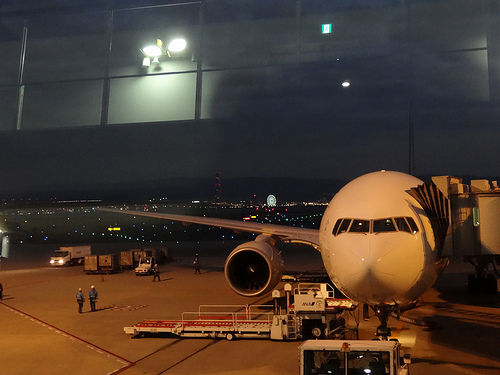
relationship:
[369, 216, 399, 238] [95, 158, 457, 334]
window on plane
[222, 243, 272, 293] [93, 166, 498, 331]
turbine of plane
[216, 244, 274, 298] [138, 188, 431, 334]
engine of plane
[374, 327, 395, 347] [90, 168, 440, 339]
wheel of plane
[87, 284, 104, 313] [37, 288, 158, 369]
person on ground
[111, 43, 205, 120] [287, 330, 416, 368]
window of vehicle